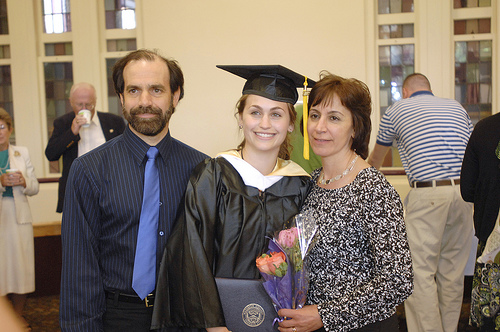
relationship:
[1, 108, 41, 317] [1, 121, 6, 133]
woman has glasses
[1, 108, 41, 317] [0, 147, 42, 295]
woman wearing white dress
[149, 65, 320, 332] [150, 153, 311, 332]
woman has graduation gown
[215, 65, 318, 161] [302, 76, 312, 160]
cap has yellow tassles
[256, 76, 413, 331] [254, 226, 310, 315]
woman has flowers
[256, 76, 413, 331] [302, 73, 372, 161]
woman has hair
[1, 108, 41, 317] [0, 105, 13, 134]
woman has hair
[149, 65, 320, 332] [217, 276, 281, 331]
woman holding graduation document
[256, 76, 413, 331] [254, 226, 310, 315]
woman holding flowers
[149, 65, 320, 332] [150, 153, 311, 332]
woman wearing graduation gown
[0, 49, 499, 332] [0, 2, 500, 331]
people inside a building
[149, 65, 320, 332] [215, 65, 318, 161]
woman wearing black cap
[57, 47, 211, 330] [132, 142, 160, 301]
man wearing blue tie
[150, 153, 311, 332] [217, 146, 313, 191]
graduation gown has white collar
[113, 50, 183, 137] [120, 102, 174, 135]
man's face has a beard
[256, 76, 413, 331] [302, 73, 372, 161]
woman has brown hair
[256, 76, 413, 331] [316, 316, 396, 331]
woman wearing brown pants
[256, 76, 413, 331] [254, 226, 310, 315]
woman has roses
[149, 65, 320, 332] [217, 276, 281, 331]
woman has a diploma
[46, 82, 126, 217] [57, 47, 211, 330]
man behind man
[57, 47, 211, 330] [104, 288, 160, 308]
man wearing a belt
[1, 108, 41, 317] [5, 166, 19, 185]
woman has cup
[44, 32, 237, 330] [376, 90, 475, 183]
man wearing shirt